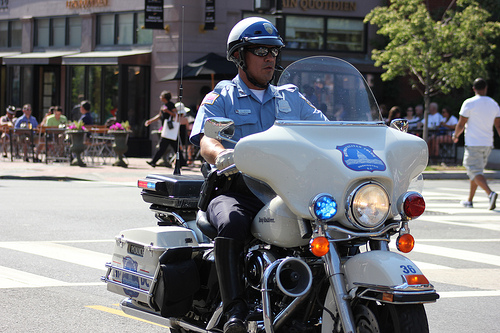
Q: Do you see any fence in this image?
A: No, there are no fences.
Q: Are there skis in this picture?
A: No, there are no skis.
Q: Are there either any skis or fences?
A: No, there are no skis or fences.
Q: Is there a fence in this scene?
A: No, there are no fences.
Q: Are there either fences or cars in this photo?
A: No, there are no fences or cars.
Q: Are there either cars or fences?
A: No, there are no fences or cars.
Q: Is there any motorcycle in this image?
A: Yes, there is a motorcycle.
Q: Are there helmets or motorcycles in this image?
A: Yes, there is a motorcycle.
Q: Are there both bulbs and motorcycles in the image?
A: No, there is a motorcycle but no light bulbs.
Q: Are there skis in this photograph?
A: No, there are no skis.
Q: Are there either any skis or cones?
A: No, there are no skis or cones.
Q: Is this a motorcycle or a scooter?
A: This is a motorcycle.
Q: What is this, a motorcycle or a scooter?
A: This is a motorcycle.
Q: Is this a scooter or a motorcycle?
A: This is a motorcycle.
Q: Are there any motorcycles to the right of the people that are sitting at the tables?
A: Yes, there is a motorcycle to the right of the people.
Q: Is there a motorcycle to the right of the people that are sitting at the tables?
A: Yes, there is a motorcycle to the right of the people.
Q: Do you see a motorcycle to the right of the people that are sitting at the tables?
A: Yes, there is a motorcycle to the right of the people.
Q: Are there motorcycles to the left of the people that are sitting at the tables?
A: No, the motorcycle is to the right of the people.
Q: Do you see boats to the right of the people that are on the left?
A: No, there is a motorcycle to the right of the people.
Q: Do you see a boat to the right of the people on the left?
A: No, there is a motorcycle to the right of the people.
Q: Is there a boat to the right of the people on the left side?
A: No, there is a motorcycle to the right of the people.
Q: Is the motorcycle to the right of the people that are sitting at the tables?
A: Yes, the motorcycle is to the right of the people.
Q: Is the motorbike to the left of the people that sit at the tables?
A: No, the motorbike is to the right of the people.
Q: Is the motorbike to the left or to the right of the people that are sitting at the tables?
A: The motorbike is to the right of the people.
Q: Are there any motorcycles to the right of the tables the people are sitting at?
A: Yes, there is a motorcycle to the right of the tables.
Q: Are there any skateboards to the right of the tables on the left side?
A: No, there is a motorcycle to the right of the tables.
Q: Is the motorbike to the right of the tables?
A: Yes, the motorbike is to the right of the tables.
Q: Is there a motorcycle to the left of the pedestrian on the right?
A: Yes, there is a motorcycle to the left of the pedestrian.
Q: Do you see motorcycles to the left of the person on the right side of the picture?
A: Yes, there is a motorcycle to the left of the pedestrian.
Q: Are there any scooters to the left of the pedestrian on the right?
A: No, there is a motorcycle to the left of the pedestrian.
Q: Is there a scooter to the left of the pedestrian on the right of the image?
A: No, there is a motorcycle to the left of the pedestrian.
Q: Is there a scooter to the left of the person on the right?
A: No, there is a motorcycle to the left of the pedestrian.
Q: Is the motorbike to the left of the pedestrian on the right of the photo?
A: Yes, the motorbike is to the left of the pedestrian.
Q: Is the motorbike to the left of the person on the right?
A: Yes, the motorbike is to the left of the pedestrian.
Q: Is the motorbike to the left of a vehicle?
A: No, the motorbike is to the left of the pedestrian.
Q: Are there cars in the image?
A: No, there are no cars.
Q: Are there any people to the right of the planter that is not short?
A: Yes, there is a person to the right of the planter.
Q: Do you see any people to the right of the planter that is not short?
A: Yes, there is a person to the right of the planter.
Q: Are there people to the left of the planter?
A: No, the person is to the right of the planter.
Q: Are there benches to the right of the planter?
A: No, there is a person to the right of the planter.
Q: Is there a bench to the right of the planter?
A: No, there is a person to the right of the planter.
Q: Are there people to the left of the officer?
A: Yes, there is a person to the left of the officer.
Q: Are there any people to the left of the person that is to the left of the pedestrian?
A: Yes, there is a person to the left of the officer.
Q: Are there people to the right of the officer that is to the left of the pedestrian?
A: No, the person is to the left of the officer.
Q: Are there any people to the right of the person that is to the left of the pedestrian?
A: No, the person is to the left of the officer.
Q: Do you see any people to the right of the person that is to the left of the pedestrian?
A: No, the person is to the left of the officer.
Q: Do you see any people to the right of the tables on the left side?
A: Yes, there is a person to the right of the tables.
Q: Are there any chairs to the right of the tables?
A: No, there is a person to the right of the tables.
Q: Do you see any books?
A: No, there are no books.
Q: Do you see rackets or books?
A: No, there are no books or rackets.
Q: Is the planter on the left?
A: Yes, the planter is on the left of the image.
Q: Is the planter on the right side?
A: No, the planter is on the left of the image.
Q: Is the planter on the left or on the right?
A: The planter is on the left of the image.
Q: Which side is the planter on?
A: The planter is on the left of the image.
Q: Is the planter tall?
A: Yes, the planter is tall.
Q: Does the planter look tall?
A: Yes, the planter is tall.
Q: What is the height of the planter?
A: The planter is tall.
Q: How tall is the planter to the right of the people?
A: The planter is tall.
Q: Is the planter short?
A: No, the planter is tall.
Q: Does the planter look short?
A: No, the planter is tall.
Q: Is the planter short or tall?
A: The planter is tall.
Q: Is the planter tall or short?
A: The planter is tall.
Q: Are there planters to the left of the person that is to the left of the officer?
A: Yes, there is a planter to the left of the person.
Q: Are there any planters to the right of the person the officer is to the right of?
A: No, the planter is to the left of the person.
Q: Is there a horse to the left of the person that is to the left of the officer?
A: No, there is a planter to the left of the person.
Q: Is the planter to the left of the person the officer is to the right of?
A: Yes, the planter is to the left of the person.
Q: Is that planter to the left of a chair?
A: No, the planter is to the left of the person.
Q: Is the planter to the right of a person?
A: No, the planter is to the left of a person.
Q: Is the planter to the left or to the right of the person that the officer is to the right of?
A: The planter is to the left of the person.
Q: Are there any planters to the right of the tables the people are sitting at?
A: Yes, there is a planter to the right of the tables.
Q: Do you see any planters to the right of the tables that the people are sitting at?
A: Yes, there is a planter to the right of the tables.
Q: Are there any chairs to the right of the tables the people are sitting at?
A: No, there is a planter to the right of the tables.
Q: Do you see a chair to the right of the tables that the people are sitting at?
A: No, there is a planter to the right of the tables.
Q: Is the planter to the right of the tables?
A: Yes, the planter is to the right of the tables.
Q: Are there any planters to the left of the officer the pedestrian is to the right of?
A: Yes, there is a planter to the left of the officer.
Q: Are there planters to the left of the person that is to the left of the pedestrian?
A: Yes, there is a planter to the left of the officer.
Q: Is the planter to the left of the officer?
A: Yes, the planter is to the left of the officer.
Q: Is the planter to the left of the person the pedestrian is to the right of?
A: Yes, the planter is to the left of the officer.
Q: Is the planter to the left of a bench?
A: No, the planter is to the left of the officer.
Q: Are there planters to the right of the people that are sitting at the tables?
A: Yes, there is a planter to the right of the people.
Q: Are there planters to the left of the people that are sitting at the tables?
A: No, the planter is to the right of the people.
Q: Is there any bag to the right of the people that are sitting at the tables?
A: No, there is a planter to the right of the people.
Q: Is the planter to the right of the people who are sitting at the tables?
A: Yes, the planter is to the right of the people.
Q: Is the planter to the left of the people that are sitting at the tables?
A: No, the planter is to the right of the people.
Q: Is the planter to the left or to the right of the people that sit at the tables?
A: The planter is to the right of the people.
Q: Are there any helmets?
A: Yes, there is a helmet.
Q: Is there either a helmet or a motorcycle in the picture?
A: Yes, there is a helmet.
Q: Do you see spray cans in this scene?
A: No, there are no spray cans.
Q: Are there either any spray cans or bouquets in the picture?
A: No, there are no spray cans or bouquets.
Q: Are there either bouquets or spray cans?
A: No, there are no spray cans or bouquets.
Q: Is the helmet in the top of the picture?
A: Yes, the helmet is in the top of the image.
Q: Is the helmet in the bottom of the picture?
A: No, the helmet is in the top of the image.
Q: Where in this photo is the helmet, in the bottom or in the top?
A: The helmet is in the top of the image.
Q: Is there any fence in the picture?
A: No, there are no fences.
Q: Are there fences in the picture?
A: No, there are no fences.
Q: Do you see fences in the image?
A: No, there are no fences.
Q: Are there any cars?
A: No, there are no cars.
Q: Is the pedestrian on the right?
A: Yes, the pedestrian is on the right of the image.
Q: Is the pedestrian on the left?
A: No, the pedestrian is on the right of the image.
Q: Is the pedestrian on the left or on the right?
A: The pedestrian is on the right of the image.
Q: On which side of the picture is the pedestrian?
A: The pedestrian is on the right of the image.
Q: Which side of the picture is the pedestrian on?
A: The pedestrian is on the right of the image.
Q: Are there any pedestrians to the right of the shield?
A: Yes, there is a pedestrian to the right of the shield.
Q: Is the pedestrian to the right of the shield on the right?
A: Yes, the pedestrian is to the right of the shield.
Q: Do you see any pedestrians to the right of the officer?
A: Yes, there is a pedestrian to the right of the officer.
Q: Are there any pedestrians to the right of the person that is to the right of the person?
A: Yes, there is a pedestrian to the right of the officer.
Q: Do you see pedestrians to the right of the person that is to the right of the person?
A: Yes, there is a pedestrian to the right of the officer.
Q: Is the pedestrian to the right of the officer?
A: Yes, the pedestrian is to the right of the officer.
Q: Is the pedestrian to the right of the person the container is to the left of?
A: Yes, the pedestrian is to the right of the officer.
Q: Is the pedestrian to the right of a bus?
A: No, the pedestrian is to the right of the officer.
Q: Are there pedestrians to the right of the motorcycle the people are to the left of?
A: Yes, there is a pedestrian to the right of the motorbike.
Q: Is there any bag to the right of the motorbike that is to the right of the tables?
A: No, there is a pedestrian to the right of the motorcycle.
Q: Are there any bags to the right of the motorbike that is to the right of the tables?
A: No, there is a pedestrian to the right of the motorcycle.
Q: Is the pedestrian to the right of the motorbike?
A: Yes, the pedestrian is to the right of the motorbike.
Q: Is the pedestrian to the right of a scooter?
A: No, the pedestrian is to the right of the motorbike.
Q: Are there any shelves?
A: No, there are no shelves.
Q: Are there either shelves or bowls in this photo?
A: No, there are no shelves or bowls.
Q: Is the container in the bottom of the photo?
A: Yes, the container is in the bottom of the image.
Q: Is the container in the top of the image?
A: No, the container is in the bottom of the image.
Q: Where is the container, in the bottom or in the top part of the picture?
A: The container is in the bottom of the image.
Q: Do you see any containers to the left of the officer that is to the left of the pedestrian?
A: Yes, there is a container to the left of the officer.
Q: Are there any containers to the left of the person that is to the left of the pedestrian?
A: Yes, there is a container to the left of the officer.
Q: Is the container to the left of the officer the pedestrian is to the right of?
A: Yes, the container is to the left of the officer.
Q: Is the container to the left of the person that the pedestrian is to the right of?
A: Yes, the container is to the left of the officer.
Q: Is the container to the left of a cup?
A: No, the container is to the left of the officer.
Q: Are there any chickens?
A: No, there are no chickens.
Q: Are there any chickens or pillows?
A: No, there are no chickens or pillows.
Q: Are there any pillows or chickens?
A: No, there are no chickens or pillows.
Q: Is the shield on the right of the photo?
A: Yes, the shield is on the right of the image.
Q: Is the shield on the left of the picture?
A: No, the shield is on the right of the image.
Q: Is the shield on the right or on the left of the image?
A: The shield is on the right of the image.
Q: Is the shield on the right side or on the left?
A: The shield is on the right of the image.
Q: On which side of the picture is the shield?
A: The shield is on the right of the image.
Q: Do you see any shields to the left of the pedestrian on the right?
A: Yes, there is a shield to the left of the pedestrian.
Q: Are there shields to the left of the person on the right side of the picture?
A: Yes, there is a shield to the left of the pedestrian.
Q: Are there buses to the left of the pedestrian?
A: No, there is a shield to the left of the pedestrian.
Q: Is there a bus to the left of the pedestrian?
A: No, there is a shield to the left of the pedestrian.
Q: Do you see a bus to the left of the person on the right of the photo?
A: No, there is a shield to the left of the pedestrian.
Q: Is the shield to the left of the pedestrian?
A: Yes, the shield is to the left of the pedestrian.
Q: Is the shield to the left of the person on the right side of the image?
A: Yes, the shield is to the left of the pedestrian.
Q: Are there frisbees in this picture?
A: No, there are no frisbees.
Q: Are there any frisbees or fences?
A: No, there are no frisbees or fences.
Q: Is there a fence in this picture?
A: No, there are no fences.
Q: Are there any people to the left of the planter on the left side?
A: Yes, there are people to the left of the planter.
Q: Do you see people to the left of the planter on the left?
A: Yes, there are people to the left of the planter.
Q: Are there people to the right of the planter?
A: No, the people are to the left of the planter.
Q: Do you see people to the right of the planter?
A: No, the people are to the left of the planter.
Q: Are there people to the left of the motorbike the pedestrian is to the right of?
A: Yes, there are people to the left of the motorbike.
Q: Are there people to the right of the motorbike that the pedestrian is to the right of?
A: No, the people are to the left of the motorcycle.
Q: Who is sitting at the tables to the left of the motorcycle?
A: The people are sitting at the tables.